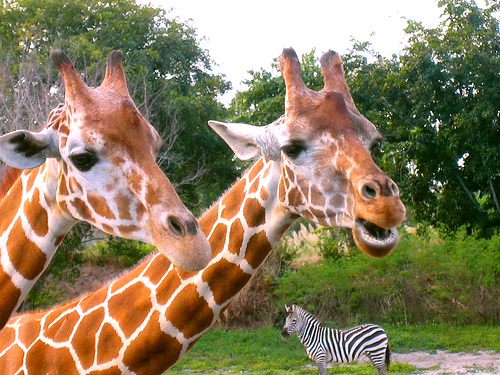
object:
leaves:
[358, 42, 366, 48]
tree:
[214, 46, 397, 236]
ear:
[204, 119, 263, 164]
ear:
[0, 128, 55, 172]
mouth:
[353, 214, 401, 249]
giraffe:
[0, 45, 212, 332]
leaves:
[0, 26, 6, 33]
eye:
[278, 140, 309, 161]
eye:
[367, 137, 383, 155]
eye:
[64, 146, 100, 173]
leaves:
[458, 209, 465, 216]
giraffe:
[0, 46, 408, 374]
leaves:
[457, 138, 469, 147]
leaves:
[481, 104, 488, 109]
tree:
[374, 0, 499, 240]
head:
[277, 300, 307, 340]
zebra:
[278, 303, 392, 374]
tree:
[0, 0, 241, 317]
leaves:
[426, 75, 438, 81]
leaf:
[144, 51, 147, 54]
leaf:
[157, 56, 160, 61]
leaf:
[160, 38, 164, 42]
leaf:
[169, 46, 175, 50]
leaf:
[160, 65, 166, 69]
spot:
[240, 230, 272, 271]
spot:
[241, 196, 266, 228]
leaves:
[190, 106, 204, 116]